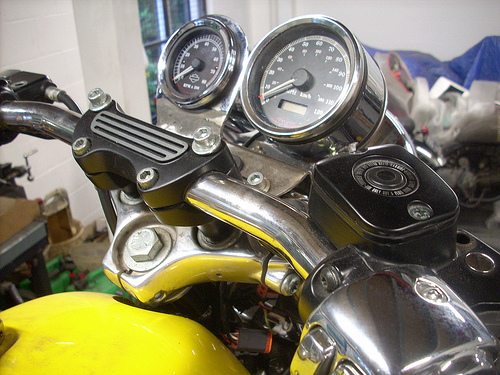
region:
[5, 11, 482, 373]
front of a yellow motorcycle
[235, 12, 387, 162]
speedometer on a motorcycle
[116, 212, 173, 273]
large metal bolt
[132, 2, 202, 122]
window behind motorcycle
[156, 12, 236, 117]
tachometer on a motorcycle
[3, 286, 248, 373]
bright yellow petrol tank on a motorcycle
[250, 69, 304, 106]
white needle with a red tip on a speedometer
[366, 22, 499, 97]
blue tarp in the background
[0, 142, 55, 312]
edge of a workbench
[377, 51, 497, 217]
cluttered area in front of motorcycle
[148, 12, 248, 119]
RPM gauge on a motorcycle.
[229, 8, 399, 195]
The speed gauge for a motorcycle.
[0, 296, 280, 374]
Yellow painted gas tank for a motorcycle.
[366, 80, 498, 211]
An engine on the floor.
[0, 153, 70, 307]
Corner of a work bench.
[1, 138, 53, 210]
Vice grips on the edge of the work bench.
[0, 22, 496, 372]
A yellow motorcycle.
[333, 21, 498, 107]
A blue tarp covering some items.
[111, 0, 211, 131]
A window in the corner of the garage.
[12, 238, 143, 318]
Green power supplies on the ground.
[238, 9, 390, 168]
A shiny silver speedometer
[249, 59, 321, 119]
a speedometer needle with a red tip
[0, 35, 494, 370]
shiny silver handles of a motorcycle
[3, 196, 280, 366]
the front of a yellow motorcycle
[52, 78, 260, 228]
a black clamp holding the handle bars in place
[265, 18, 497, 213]
a pile of junk behind the motorcycle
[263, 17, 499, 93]
a blue tarp over the pile of junk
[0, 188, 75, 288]
a metal work table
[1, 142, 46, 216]
a vice grip secured to a table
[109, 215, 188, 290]
a very large bolt and washer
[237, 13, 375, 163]
Speedometer gauge is attached to handlebar.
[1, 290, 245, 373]
Gas tank on the motorcycle is yellow.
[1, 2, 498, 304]
Motorcycle is sitting indoors.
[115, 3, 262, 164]
There's a window in the room.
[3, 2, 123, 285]
Left wall is made from cement blocks.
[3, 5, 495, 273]
The walls are painted white.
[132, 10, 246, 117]
Tachometer on motorcycle is on left side of handlebar.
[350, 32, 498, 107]
There's a blue tarp against rear wall.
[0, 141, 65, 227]
There's a vise attached to a bench on the left.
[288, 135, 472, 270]
There's a square, black box next to speedometer.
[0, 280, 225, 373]
yellow fuel tank on motorcycle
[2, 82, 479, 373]
chrome handlebars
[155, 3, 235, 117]
rev counter on motorcycle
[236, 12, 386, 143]
odometer on motorcycle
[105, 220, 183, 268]
large motorcycle handlebar nut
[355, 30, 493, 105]
blue tarp against back wall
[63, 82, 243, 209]
four nuts to keep handlebars on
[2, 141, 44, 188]
vice on workbench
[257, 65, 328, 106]
Needle on motorcycle speedometer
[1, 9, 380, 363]
motorcycle with yellow fueltank